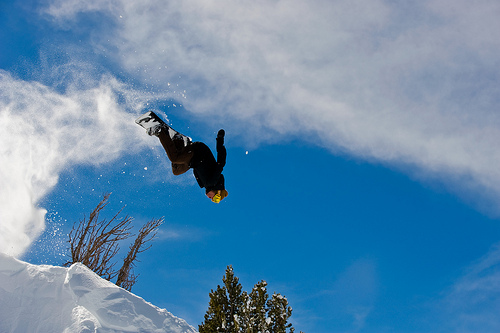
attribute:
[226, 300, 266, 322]
leaves — green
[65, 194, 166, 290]
tree branches — bare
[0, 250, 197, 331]
snow — white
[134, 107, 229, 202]
person — upside down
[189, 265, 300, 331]
tree — pointy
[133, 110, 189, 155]
snowboard — dark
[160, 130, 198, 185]
pants — brown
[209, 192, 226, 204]
goggles — yellow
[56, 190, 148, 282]
branches — tall, leafless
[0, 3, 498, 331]
sky — blue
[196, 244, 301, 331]
tree — green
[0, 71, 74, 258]
snow — white 